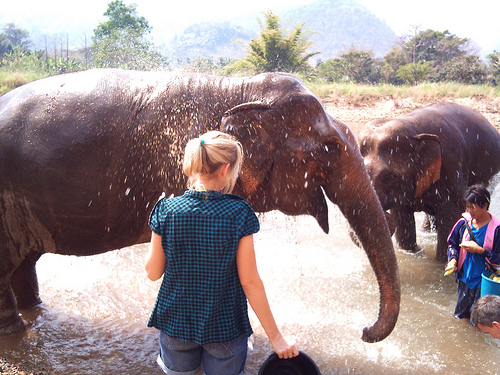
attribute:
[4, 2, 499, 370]
picture — taken outside, taken during the day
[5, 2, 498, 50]
sun — out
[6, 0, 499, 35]
sky — bright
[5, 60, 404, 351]
elephant — happy, brown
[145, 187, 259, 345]
shirt — checkered, black, green, plaid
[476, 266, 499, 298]
bucket — blue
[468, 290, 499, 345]
man — bending down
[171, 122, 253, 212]
head — blond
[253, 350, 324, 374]
bucket — black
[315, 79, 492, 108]
grass — tall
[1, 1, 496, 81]
vegetation — tall